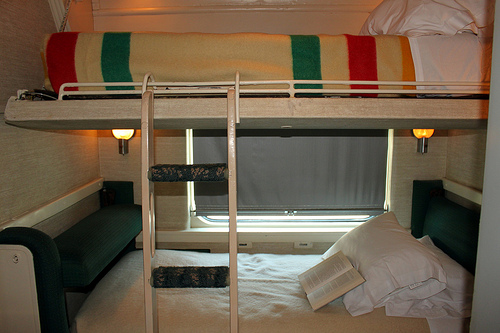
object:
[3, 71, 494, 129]
bed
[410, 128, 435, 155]
light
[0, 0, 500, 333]
cabin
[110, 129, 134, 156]
light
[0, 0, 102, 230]
wall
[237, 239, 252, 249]
outlets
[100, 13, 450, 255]
wall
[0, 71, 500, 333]
bunk beds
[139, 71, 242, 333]
ladder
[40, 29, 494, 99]
blanket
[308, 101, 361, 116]
green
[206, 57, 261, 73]
yellow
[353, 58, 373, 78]
red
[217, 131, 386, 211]
shade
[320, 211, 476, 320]
top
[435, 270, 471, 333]
bottom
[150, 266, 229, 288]
first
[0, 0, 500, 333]
train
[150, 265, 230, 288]
fur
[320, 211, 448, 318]
pillow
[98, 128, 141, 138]
yellow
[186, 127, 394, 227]
blind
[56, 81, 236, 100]
lines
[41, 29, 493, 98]
sheet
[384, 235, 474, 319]
pillow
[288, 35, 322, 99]
stripe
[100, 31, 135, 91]
stripe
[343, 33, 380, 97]
stripe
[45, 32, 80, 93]
stripe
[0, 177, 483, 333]
bed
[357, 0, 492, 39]
pillow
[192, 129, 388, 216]
curtain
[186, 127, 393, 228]
window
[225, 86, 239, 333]
pole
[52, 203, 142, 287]
cushion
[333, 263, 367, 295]
corner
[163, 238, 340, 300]
light